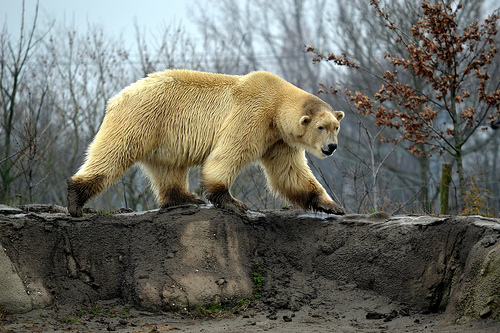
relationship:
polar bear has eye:
[65, 68, 346, 217] [317, 125, 325, 131]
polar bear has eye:
[65, 68, 346, 217] [335, 127, 338, 131]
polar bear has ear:
[65, 68, 346, 217] [298, 115, 312, 126]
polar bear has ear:
[65, 68, 346, 217] [336, 111, 345, 122]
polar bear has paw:
[65, 68, 346, 217] [309, 198, 347, 215]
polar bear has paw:
[65, 68, 346, 217] [205, 189, 250, 212]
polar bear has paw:
[65, 68, 346, 217] [158, 193, 206, 208]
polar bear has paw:
[65, 68, 346, 217] [65, 175, 84, 219]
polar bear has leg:
[65, 68, 346, 217] [260, 139, 335, 203]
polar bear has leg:
[65, 68, 346, 217] [200, 122, 262, 190]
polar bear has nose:
[65, 68, 346, 217] [329, 143, 338, 150]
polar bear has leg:
[65, 68, 346, 217] [138, 162, 205, 210]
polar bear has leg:
[65, 68, 346, 217] [80, 128, 139, 190]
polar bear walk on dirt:
[65, 68, 346, 217] [1, 204, 499, 333]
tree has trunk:
[308, 0, 499, 216] [449, 87, 470, 214]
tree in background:
[2, 1, 57, 205] [2, 1, 499, 204]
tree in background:
[43, 12, 113, 174] [2, 1, 499, 204]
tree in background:
[308, 0, 499, 216] [2, 1, 499, 204]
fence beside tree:
[244, 163, 499, 216] [308, 0, 499, 216]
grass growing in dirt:
[82, 200, 115, 215] [1, 204, 499, 333]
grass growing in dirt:
[63, 297, 132, 324] [1, 204, 499, 333]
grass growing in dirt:
[195, 300, 245, 309] [1, 204, 499, 333]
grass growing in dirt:
[252, 261, 269, 300] [1, 204, 499, 333]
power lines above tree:
[2, 52, 387, 75] [43, 12, 113, 174]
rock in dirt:
[281, 314, 292, 322] [1, 204, 499, 333]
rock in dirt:
[248, 320, 256, 327] [1, 204, 499, 333]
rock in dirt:
[216, 278, 226, 286] [1, 204, 499, 333]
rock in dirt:
[412, 317, 422, 324] [1, 204, 499, 333]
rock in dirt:
[119, 319, 127, 325] [1, 204, 499, 333]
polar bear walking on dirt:
[65, 68, 346, 217] [1, 204, 499, 333]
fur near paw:
[280, 189, 317, 206] [309, 198, 347, 215]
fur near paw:
[206, 181, 231, 200] [205, 189, 250, 212]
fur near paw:
[161, 185, 185, 197] [158, 193, 206, 208]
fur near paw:
[73, 174, 106, 201] [65, 175, 84, 219]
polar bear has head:
[65, 68, 346, 217] [299, 98, 343, 158]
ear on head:
[298, 115, 312, 126] [299, 98, 343, 158]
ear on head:
[336, 111, 345, 122] [299, 98, 343, 158]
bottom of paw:
[67, 182, 77, 214] [65, 175, 84, 219]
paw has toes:
[65, 175, 84, 219] [69, 209, 83, 217]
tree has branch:
[308, 0, 499, 216] [462, 102, 491, 145]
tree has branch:
[308, 0, 499, 216] [427, 121, 457, 152]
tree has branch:
[308, 0, 499, 216] [439, 96, 455, 123]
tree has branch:
[308, 0, 499, 216] [454, 30, 493, 89]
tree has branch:
[308, 0, 499, 216] [455, 41, 475, 66]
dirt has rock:
[1, 204, 499, 333] [412, 317, 422, 324]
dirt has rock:
[1, 204, 499, 333] [281, 314, 292, 322]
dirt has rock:
[1, 204, 499, 333] [248, 320, 256, 327]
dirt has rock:
[1, 204, 499, 333] [216, 278, 226, 286]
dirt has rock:
[1, 204, 499, 333] [119, 319, 127, 325]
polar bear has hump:
[65, 68, 346, 217] [236, 71, 291, 87]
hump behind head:
[236, 71, 291, 87] [299, 98, 343, 158]